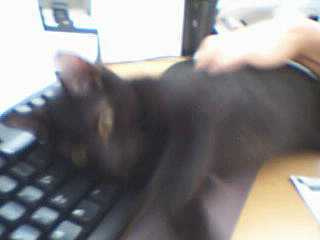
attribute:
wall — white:
[113, 8, 169, 53]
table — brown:
[242, 156, 316, 239]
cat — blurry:
[64, 98, 232, 233]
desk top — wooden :
[249, 165, 307, 237]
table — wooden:
[252, 186, 301, 225]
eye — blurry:
[94, 111, 117, 134]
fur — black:
[189, 84, 252, 129]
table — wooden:
[95, 58, 317, 239]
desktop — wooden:
[211, 142, 308, 239]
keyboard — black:
[3, 67, 131, 238]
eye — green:
[97, 104, 115, 136]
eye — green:
[70, 143, 87, 172]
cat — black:
[19, 55, 286, 197]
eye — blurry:
[71, 150, 87, 165]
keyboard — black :
[3, 139, 111, 233]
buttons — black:
[6, 148, 125, 238]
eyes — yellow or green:
[51, 87, 125, 178]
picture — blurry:
[0, 0, 315, 239]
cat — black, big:
[7, 39, 318, 236]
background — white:
[1, 3, 182, 103]